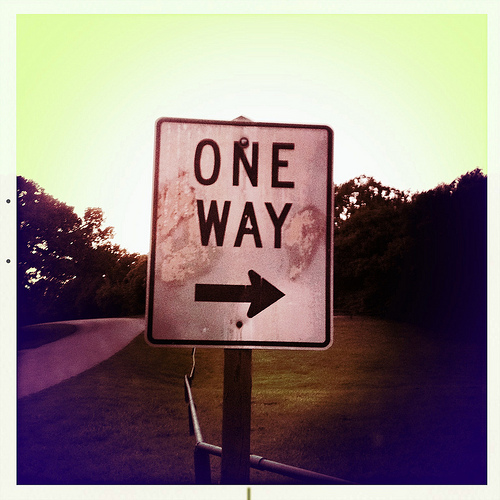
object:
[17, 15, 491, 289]
sky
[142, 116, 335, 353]
sign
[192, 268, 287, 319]
arrow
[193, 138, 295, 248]
lettering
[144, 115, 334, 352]
edging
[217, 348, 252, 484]
pole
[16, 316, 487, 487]
grass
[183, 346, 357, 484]
fence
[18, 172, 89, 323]
tree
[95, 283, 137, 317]
tree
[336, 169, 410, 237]
tree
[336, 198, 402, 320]
tree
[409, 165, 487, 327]
tree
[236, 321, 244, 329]
bolt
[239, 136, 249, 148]
bolt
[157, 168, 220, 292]
mark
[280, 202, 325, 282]
mark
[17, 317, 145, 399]
sidewalk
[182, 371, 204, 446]
railing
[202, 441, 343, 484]
railing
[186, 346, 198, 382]
railing